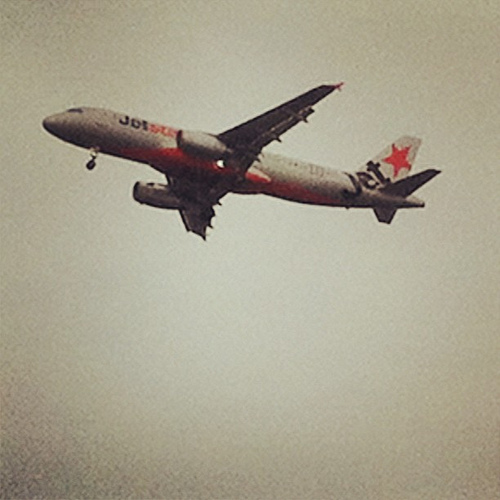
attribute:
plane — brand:
[36, 31, 497, 305]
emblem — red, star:
[335, 129, 445, 210]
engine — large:
[168, 119, 278, 189]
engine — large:
[123, 170, 244, 261]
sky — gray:
[2, 1, 499, 498]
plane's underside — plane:
[58, 131, 413, 208]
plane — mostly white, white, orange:
[46, 75, 441, 244]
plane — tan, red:
[18, 61, 473, 246]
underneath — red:
[109, 133, 310, 212]